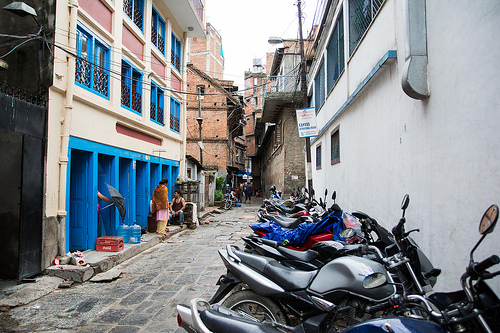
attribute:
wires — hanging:
[262, 3, 328, 93]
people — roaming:
[171, 171, 269, 222]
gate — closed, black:
[0, 77, 47, 285]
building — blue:
[33, 26, 258, 250]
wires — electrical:
[34, 30, 309, 110]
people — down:
[212, 166, 254, 211]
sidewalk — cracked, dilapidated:
[43, 257, 101, 288]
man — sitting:
[166, 186, 190, 229]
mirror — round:
[477, 204, 497, 239]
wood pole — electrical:
[294, 3, 310, 96]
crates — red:
[90, 232, 126, 249]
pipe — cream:
[55, 96, 77, 208]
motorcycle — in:
[181, 206, 498, 327]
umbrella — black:
[103, 179, 127, 219]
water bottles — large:
[110, 206, 157, 256]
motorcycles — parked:
[175, 183, 498, 331]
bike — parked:
[244, 222, 431, 266]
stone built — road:
[127, 257, 201, 299]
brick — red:
[66, 331, 81, 333]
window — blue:
[71, 51, 92, 86]